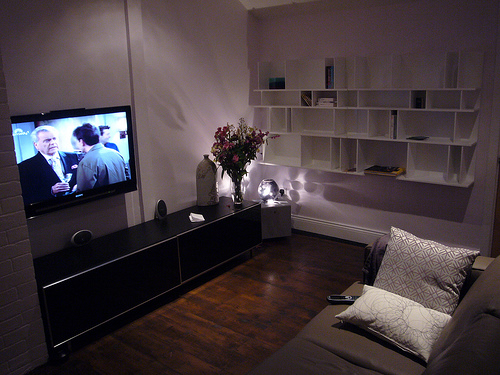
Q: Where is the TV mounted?
A: Wall.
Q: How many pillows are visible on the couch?
A: 2.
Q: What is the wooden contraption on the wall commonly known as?
A: Shelves.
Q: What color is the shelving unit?
A: White.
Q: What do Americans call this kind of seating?
A: Couch.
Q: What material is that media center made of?
A: Wood.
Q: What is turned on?
A: TV screen.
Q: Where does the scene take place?
A: In a living room.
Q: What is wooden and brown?
A: The floor.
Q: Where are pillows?
A: On a couch.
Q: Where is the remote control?
A: On the couch.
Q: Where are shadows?
A: On the wall.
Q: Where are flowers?
A: In a vase.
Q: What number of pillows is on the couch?
A: Two.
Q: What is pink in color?
A: Flowers.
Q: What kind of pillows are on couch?
A: Decorative.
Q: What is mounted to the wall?
A: Flat screen.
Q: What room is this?
A: Living room.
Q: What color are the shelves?
A: White.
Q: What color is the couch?
A: Brown.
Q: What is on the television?
A: A show.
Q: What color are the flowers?
A: Red.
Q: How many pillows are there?
A: Two.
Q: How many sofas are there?
A: One.